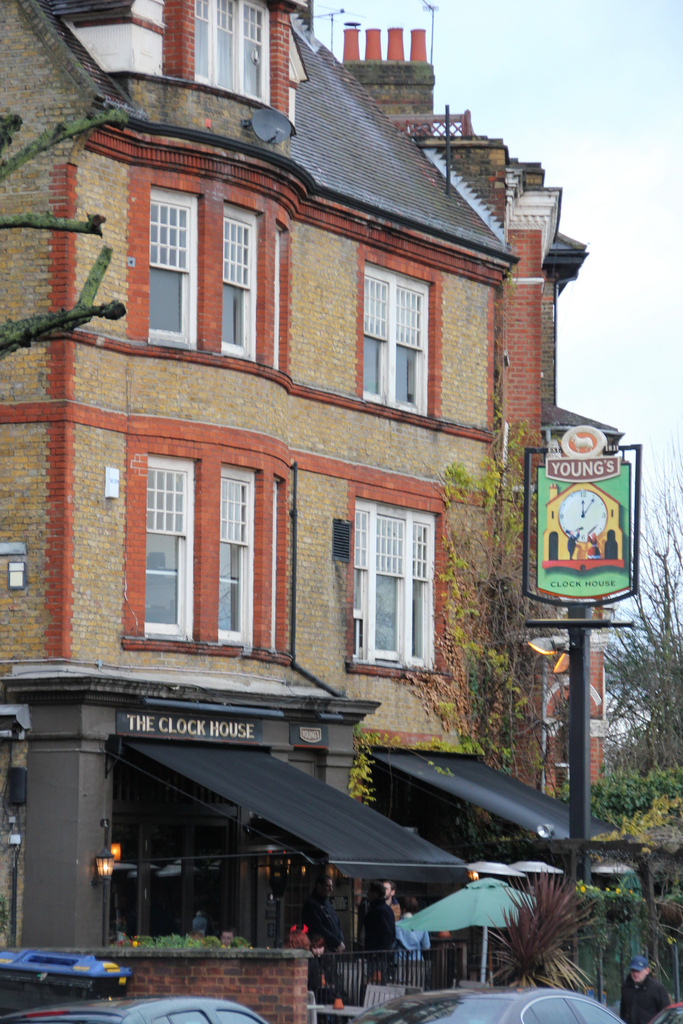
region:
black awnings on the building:
[139, 731, 634, 877]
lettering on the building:
[128, 709, 256, 742]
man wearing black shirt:
[617, 951, 668, 1021]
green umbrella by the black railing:
[408, 874, 543, 941]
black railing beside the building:
[314, 925, 632, 1020]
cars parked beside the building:
[31, 988, 681, 1023]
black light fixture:
[93, 840, 122, 887]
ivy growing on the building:
[317, 363, 560, 840]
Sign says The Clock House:
[110, 704, 270, 746]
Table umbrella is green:
[384, 865, 552, 977]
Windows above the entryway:
[112, 435, 301, 659]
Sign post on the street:
[514, 411, 652, 614]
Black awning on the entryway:
[101, 719, 480, 901]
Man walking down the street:
[614, 943, 666, 1020]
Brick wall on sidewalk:
[0, 937, 313, 1019]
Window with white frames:
[334, 483, 448, 679]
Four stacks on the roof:
[330, 17, 437, 67]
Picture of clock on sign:
[556, 487, 611, 540]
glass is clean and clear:
[142, 467, 185, 534]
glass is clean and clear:
[145, 530, 176, 569]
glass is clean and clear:
[145, 571, 177, 624]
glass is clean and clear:
[221, 480, 247, 541]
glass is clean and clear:
[374, 515, 401, 575]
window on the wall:
[150, 184, 200, 346]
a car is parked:
[10, 999, 270, 1022]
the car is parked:
[346, 988, 627, 1021]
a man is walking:
[622, 956, 666, 1022]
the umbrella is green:
[392, 872, 537, 933]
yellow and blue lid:
[3, 950, 127, 974]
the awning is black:
[113, 733, 468, 882]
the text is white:
[124, 714, 251, 741]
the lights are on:
[96, 841, 122, 876]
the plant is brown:
[485, 871, 597, 989]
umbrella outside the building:
[390, 858, 546, 972]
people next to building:
[255, 844, 418, 980]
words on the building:
[94, 680, 288, 779]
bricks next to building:
[122, 946, 311, 1009]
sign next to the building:
[461, 410, 656, 674]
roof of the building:
[265, 39, 441, 223]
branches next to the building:
[616, 508, 682, 717]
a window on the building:
[355, 527, 419, 618]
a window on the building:
[269, 488, 280, 646]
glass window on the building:
[138, 567, 178, 626]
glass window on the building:
[138, 530, 171, 569]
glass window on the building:
[212, 578, 239, 633]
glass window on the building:
[214, 540, 243, 581]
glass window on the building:
[374, 575, 397, 649]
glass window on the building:
[145, 268, 183, 333]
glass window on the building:
[218, 279, 239, 342]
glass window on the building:
[362, 332, 377, 397]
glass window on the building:
[393, 344, 412, 408]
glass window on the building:
[374, 578, 398, 653]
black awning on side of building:
[140, 738, 470, 896]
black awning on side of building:
[391, 731, 622, 850]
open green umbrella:
[401, 865, 570, 945]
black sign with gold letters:
[121, 708, 261, 741]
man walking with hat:
[610, 945, 658, 1020]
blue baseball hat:
[620, 952, 652, 971]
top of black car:
[340, 969, 624, 1021]